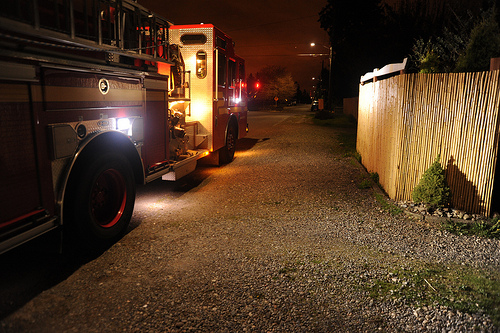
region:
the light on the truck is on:
[115, 117, 132, 132]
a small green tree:
[410, 155, 450, 212]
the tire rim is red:
[91, 168, 128, 228]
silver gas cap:
[100, 79, 110, 94]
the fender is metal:
[56, 130, 146, 225]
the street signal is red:
[253, 80, 261, 89]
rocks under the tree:
[400, 199, 467, 219]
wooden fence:
[356, 73, 495, 216]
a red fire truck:
[0, 1, 248, 251]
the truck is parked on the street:
[0, 3, 252, 267]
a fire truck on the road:
[72, 9, 414, 319]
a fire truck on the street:
[66, 26, 343, 331]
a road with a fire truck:
[123, 29, 375, 323]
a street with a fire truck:
[65, 7, 336, 268]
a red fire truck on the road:
[32, 38, 314, 278]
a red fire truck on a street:
[65, 47, 378, 320]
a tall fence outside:
[333, 17, 497, 250]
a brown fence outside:
[354, 44, 494, 220]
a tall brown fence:
[304, 28, 496, 224]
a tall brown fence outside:
[325, 41, 497, 226]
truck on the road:
[0, 1, 285, 313]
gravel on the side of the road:
[8, 102, 494, 332]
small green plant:
[401, 143, 473, 218]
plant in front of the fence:
[402, 155, 460, 209]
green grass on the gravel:
[358, 253, 498, 311]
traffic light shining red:
[251, 79, 261, 94]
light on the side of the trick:
[115, 116, 134, 128]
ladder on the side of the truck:
[1, 5, 188, 72]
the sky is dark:
[146, 2, 346, 95]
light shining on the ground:
[135, 188, 182, 216]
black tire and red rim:
[67, 135, 146, 250]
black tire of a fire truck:
[216, 118, 246, 163]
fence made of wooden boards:
[349, 60, 499, 212]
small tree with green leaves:
[407, 151, 452, 221]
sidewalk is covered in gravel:
[9, 90, 497, 332]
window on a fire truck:
[215, 50, 229, 91]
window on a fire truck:
[227, 56, 239, 93]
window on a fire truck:
[177, 29, 211, 49]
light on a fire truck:
[252, 78, 262, 91]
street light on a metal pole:
[302, 36, 340, 104]